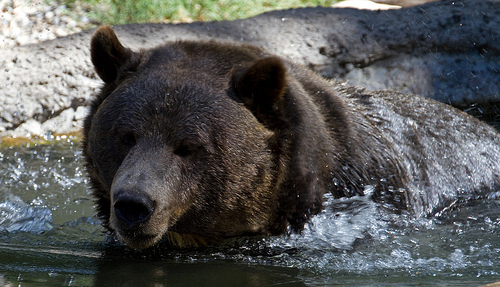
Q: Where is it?
A: This is at the river.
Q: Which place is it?
A: It is a river.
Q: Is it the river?
A: Yes, it is the river.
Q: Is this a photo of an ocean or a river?
A: It is showing a river.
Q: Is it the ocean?
A: No, it is the river.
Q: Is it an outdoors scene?
A: Yes, it is outdoors.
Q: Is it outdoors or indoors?
A: It is outdoors.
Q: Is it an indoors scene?
A: No, it is outdoors.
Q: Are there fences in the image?
A: No, there are no fences.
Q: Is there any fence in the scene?
A: No, there are no fences.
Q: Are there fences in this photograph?
A: No, there are no fences.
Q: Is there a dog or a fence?
A: No, there are no fences or dogs.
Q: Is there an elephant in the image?
A: No, there are no elephants.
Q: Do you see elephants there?
A: No, there are no elephants.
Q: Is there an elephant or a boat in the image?
A: No, there are no elephants or boats.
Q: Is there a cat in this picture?
A: No, there are no cats.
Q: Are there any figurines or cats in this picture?
A: No, there are no cats or figurines.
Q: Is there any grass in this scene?
A: Yes, there is grass.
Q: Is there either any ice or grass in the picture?
A: Yes, there is grass.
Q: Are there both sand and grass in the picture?
A: No, there is grass but no sand.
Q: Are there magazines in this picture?
A: No, there are no magazines.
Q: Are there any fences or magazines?
A: No, there are no magazines or fences.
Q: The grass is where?
A: The grass is on the river.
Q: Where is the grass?
A: The grass is on the river.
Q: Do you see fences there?
A: No, there are no fences.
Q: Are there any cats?
A: No, there are no cats.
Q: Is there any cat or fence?
A: No, there are no cats or fences.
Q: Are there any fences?
A: No, there are no fences.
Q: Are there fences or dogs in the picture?
A: No, there are no fences or dogs.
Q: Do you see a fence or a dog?
A: No, there are no fences or dogs.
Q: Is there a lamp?
A: No, there are no lamps.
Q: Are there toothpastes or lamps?
A: No, there are no lamps or toothpastes.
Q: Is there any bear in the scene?
A: Yes, there is a bear.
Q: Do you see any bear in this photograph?
A: Yes, there is a bear.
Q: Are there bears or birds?
A: Yes, there is a bear.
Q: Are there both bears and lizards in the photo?
A: No, there is a bear but no lizards.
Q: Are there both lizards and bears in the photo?
A: No, there is a bear but no lizards.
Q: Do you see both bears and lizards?
A: No, there is a bear but no lizards.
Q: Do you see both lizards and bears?
A: No, there is a bear but no lizards.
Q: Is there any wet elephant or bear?
A: Yes, there is a wet bear.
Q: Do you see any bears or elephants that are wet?
A: Yes, the bear is wet.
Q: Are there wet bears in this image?
A: Yes, there is a wet bear.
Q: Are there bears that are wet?
A: Yes, there is a bear that is wet.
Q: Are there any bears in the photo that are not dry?
A: Yes, there is a wet bear.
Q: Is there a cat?
A: No, there are no cats.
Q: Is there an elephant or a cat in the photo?
A: No, there are no cats or elephants.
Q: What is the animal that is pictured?
A: The animal is a bear.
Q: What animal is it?
A: The animal is a bear.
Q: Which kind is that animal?
A: This is a bear.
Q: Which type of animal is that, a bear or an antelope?
A: This is a bear.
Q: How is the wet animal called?
A: The animal is a bear.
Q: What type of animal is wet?
A: The animal is a bear.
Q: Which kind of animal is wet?
A: The animal is a bear.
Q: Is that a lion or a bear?
A: That is a bear.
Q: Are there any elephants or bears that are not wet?
A: No, there is a bear but it is wet.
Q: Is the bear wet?
A: Yes, the bear is wet.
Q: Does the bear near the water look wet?
A: Yes, the bear is wet.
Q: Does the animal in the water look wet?
A: Yes, the bear is wet.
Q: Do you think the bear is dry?
A: No, the bear is wet.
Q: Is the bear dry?
A: No, the bear is wet.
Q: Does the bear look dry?
A: No, the bear is wet.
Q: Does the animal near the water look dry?
A: No, the bear is wet.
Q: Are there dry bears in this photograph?
A: No, there is a bear but it is wet.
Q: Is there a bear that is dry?
A: No, there is a bear but it is wet.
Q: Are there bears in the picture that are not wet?
A: No, there is a bear but it is wet.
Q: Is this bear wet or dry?
A: The bear is wet.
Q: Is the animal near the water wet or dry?
A: The bear is wet.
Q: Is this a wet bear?
A: Yes, this is a wet bear.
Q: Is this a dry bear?
A: No, this is a wet bear.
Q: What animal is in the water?
A: The bear is in the water.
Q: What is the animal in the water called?
A: The animal is a bear.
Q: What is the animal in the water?
A: The animal is a bear.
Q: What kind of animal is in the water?
A: The animal is a bear.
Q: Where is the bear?
A: The bear is in the water.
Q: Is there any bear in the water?
A: Yes, there is a bear in the water.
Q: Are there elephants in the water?
A: No, there is a bear in the water.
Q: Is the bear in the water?
A: Yes, the bear is in the water.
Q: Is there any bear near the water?
A: Yes, there is a bear near the water.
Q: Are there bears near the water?
A: Yes, there is a bear near the water.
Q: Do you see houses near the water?
A: No, there is a bear near the water.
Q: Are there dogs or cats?
A: No, there are no cats or dogs.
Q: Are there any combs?
A: No, there are no combs.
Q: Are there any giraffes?
A: No, there are no giraffes.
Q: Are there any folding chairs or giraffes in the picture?
A: No, there are no giraffes or folding chairs.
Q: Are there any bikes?
A: No, there are no bikes.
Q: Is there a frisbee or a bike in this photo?
A: No, there are no bikes or frisbees.